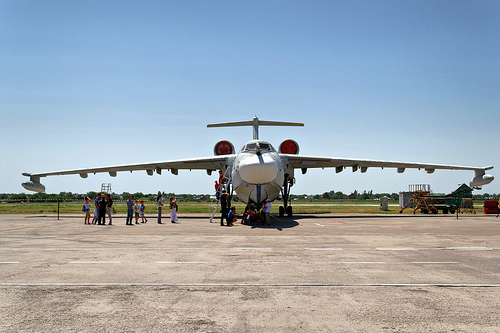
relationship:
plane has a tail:
[22, 116, 495, 220] [207, 116, 305, 142]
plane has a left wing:
[22, 116, 495, 220] [280, 152, 494, 193]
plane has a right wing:
[22, 116, 495, 220] [19, 155, 232, 194]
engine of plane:
[215, 141, 236, 157] [22, 116, 495, 220]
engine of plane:
[281, 139, 301, 155] [22, 116, 495, 220]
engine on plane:
[215, 141, 236, 157] [22, 116, 495, 220]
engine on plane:
[281, 139, 301, 155] [22, 116, 495, 220]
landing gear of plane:
[220, 192, 292, 220] [22, 116, 495, 220]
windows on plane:
[243, 142, 277, 155] [22, 116, 495, 220]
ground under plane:
[1, 215, 500, 332] [22, 116, 495, 220]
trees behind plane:
[1, 189, 499, 204] [22, 116, 495, 220]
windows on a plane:
[243, 142, 277, 155] [22, 116, 495, 220]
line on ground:
[2, 282, 499, 289] [1, 215, 500, 332]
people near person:
[126, 195, 148, 227] [169, 197, 178, 222]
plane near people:
[22, 116, 495, 220] [77, 192, 178, 227]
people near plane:
[77, 192, 178, 227] [22, 116, 495, 220]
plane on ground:
[22, 116, 495, 220] [1, 215, 500, 332]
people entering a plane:
[215, 170, 226, 202] [22, 116, 495, 220]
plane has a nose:
[22, 116, 495, 220] [239, 155, 280, 185]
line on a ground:
[2, 282, 499, 289] [1, 215, 500, 332]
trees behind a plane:
[1, 189, 499, 204] [22, 116, 495, 220]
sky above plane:
[1, 1, 500, 193] [22, 116, 495, 220]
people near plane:
[126, 195, 148, 227] [22, 116, 495, 220]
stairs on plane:
[207, 164, 234, 223] [22, 116, 495, 220]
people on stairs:
[215, 170, 226, 202] [207, 164, 234, 223]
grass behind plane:
[1, 203, 499, 216] [22, 116, 495, 220]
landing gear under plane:
[220, 192, 292, 220] [22, 116, 495, 220]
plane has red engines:
[22, 116, 495, 220] [215, 141, 300, 156]